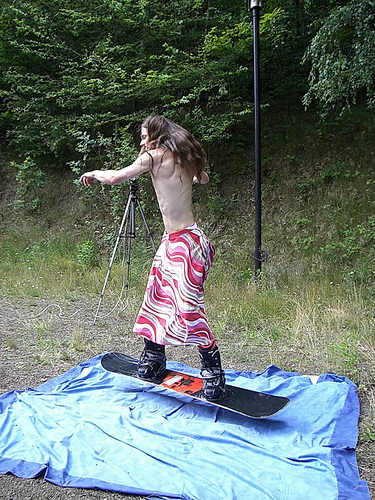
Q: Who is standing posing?
A: A man wearing a skirt.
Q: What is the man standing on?
A: A snowboard.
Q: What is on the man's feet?
A: Snowboard boots.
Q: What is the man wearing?
A: A swirled skirt.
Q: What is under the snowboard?
A: A blue blanket.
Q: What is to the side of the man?
A: A camera on a tripod.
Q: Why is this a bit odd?
A: There is no snow.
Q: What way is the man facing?
A: To his right.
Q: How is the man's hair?
A: Brown and long.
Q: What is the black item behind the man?
A: A pole.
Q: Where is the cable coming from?
A: The camera on the tripod.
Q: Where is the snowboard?
A: On blue blanket.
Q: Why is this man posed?
A: Photograph advertisement.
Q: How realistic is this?
A: Totally faked.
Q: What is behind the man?
A: A tripod.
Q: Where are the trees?
A: On the steep incline in the background.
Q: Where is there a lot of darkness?
A: Between the trees in the woods.`.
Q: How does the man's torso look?
A: Smooth, toned, and pale.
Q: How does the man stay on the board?
A: Heavy boots attach to it.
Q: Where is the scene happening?
A: In the woods.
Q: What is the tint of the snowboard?
A: Black and red.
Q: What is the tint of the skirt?
A: Red and white.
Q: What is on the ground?
A: Blue tarp.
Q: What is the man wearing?
A: No shirt.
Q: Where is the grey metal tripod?
A: On the ground.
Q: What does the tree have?
A: Green leaves.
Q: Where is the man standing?
A: On the snowboard.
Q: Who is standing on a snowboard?
A: A man.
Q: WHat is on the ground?
A: A blue cloth.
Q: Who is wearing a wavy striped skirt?
A: A man with long hair.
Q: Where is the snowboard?
A: Blue blanket.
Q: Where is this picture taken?
A: Forested area.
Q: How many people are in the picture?
A: One.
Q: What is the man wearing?
A: Skirt.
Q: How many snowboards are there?
A: One.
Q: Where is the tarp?
A: Under snowboard.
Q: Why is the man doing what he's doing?
A: Practice.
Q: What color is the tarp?
A: Blue.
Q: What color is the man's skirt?
A: Red.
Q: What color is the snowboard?
A: Black.